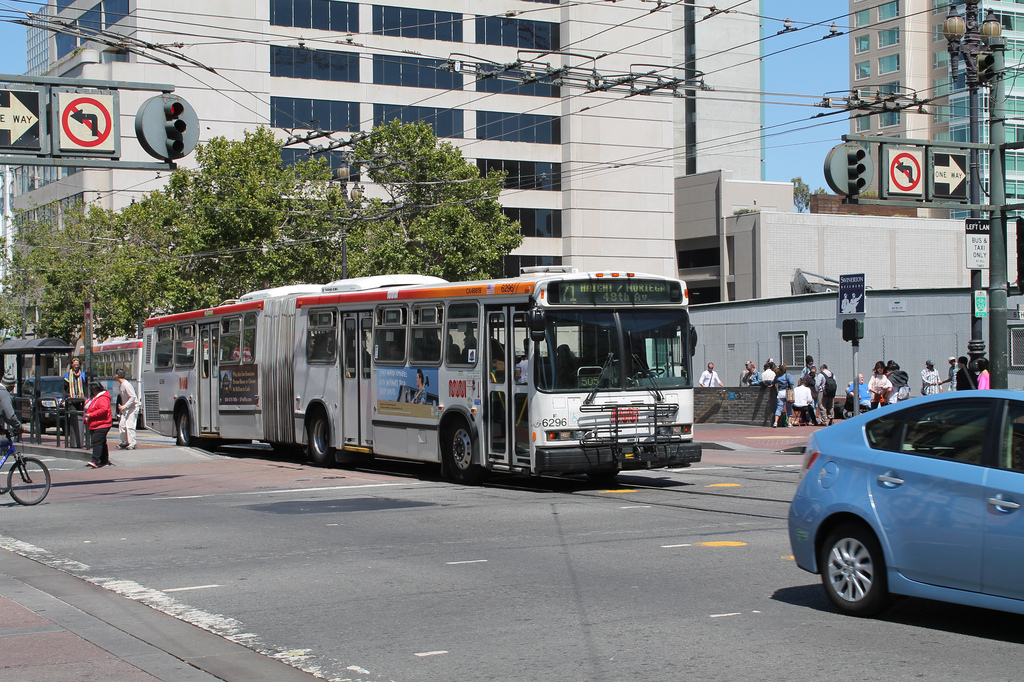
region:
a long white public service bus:
[133, 271, 703, 490]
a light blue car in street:
[783, 390, 1022, 631]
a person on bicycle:
[2, 375, 50, 508]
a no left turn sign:
[884, 150, 923, 195]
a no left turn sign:
[54, 92, 112, 151]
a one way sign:
[0, 89, 38, 150]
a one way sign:
[932, 150, 965, 201]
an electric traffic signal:
[824, 141, 878, 196]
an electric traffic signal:
[136, 93, 198, 160]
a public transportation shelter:
[9, 336, 70, 439]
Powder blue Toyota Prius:
[788, 383, 1022, 625]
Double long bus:
[136, 259, 702, 494]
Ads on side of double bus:
[212, 358, 443, 420]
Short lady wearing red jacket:
[77, 374, 113, 467]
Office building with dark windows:
[30, 0, 669, 413]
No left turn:
[46, 76, 126, 172]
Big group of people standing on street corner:
[694, 344, 1001, 425]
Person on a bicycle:
[0, 370, 61, 507]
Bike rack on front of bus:
[573, 398, 668, 440]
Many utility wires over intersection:
[11, 1, 995, 183]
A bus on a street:
[139, 270, 709, 483]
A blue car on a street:
[787, 380, 1021, 636]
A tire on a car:
[815, 504, 885, 615]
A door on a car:
[861, 384, 1001, 591]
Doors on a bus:
[472, 291, 548, 470]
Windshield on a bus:
[530, 304, 693, 388]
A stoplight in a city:
[137, 86, 211, 175]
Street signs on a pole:
[883, 133, 975, 204]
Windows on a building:
[267, 33, 372, 79]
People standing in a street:
[71, 363, 148, 462]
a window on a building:
[269, 40, 286, 85]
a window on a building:
[289, 40, 303, 79]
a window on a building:
[307, 42, 326, 81]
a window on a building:
[326, 46, 339, 81]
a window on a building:
[351, 54, 359, 84]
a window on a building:
[374, 43, 385, 86]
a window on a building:
[387, 48, 394, 83]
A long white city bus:
[125, 256, 711, 498]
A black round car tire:
[807, 500, 896, 618]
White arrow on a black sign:
[915, 137, 973, 208]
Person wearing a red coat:
[70, 371, 119, 432]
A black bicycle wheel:
[1, 443, 55, 510]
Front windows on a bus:
[523, 298, 695, 403]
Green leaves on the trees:
[1, 111, 529, 347]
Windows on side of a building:
[261, 33, 367, 94]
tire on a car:
[789, 510, 926, 619]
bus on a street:
[526, 251, 716, 487]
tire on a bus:
[402, 390, 485, 486]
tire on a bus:
[292, 389, 365, 457]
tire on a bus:
[134, 383, 223, 450]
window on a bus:
[541, 313, 697, 403]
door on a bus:
[479, 291, 541, 478]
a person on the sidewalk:
[774, 351, 833, 421]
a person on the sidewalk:
[879, 278, 921, 337]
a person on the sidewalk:
[686, 331, 716, 401]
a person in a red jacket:
[75, 383, 118, 456]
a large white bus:
[136, 281, 703, 481]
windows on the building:
[265, 41, 367, 77]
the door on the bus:
[487, 315, 536, 455]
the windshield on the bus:
[546, 323, 696, 381]